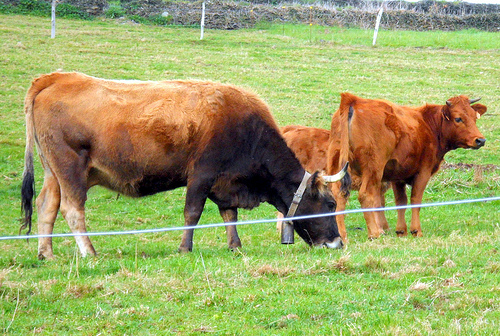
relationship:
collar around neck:
[277, 165, 310, 251] [270, 126, 307, 234]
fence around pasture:
[40, 1, 469, 57] [110, 44, 480, 75]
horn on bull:
[465, 94, 487, 108] [319, 84, 487, 234]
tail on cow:
[13, 75, 50, 242] [19, 69, 351, 259]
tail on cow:
[335, 93, 354, 193] [326, 86, 486, 242]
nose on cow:
[469, 135, 490, 154] [326, 86, 486, 242]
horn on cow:
[320, 160, 351, 187] [19, 69, 351, 259]